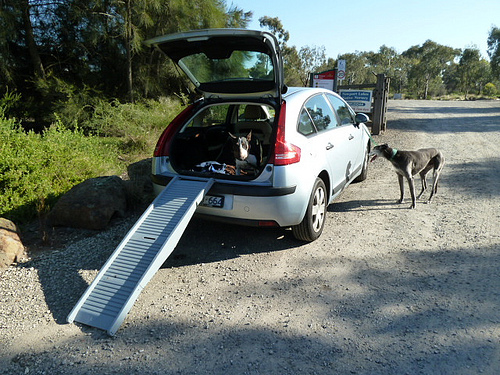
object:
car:
[142, 28, 371, 242]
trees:
[455, 44, 486, 100]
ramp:
[65, 171, 215, 339]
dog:
[374, 142, 445, 208]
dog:
[223, 128, 256, 161]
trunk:
[171, 104, 278, 183]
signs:
[336, 88, 372, 112]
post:
[370, 72, 385, 134]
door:
[148, 28, 283, 101]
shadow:
[9, 243, 500, 374]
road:
[1, 98, 500, 374]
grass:
[0, 91, 190, 223]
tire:
[292, 175, 329, 243]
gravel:
[453, 316, 464, 323]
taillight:
[270, 147, 302, 166]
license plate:
[201, 196, 222, 207]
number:
[217, 197, 224, 207]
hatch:
[160, 100, 283, 180]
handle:
[323, 142, 333, 151]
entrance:
[378, 72, 500, 121]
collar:
[388, 147, 398, 165]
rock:
[49, 175, 126, 229]